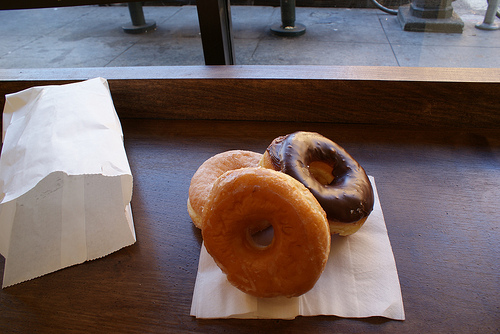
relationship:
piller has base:
[396, 2, 467, 37] [396, 2, 465, 36]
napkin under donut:
[188, 149, 414, 320] [265, 123, 382, 246]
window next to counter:
[4, 6, 500, 77] [2, 65, 499, 334]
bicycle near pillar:
[371, 3, 406, 16] [396, 2, 467, 37]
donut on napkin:
[265, 123, 382, 246] [188, 149, 414, 320]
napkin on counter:
[188, 149, 414, 320] [2, 65, 499, 334]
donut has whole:
[265, 123, 382, 246] [305, 154, 344, 191]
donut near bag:
[192, 166, 337, 306] [0, 72, 145, 287]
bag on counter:
[0, 72, 145, 287] [2, 65, 499, 334]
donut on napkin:
[192, 166, 337, 306] [188, 149, 414, 320]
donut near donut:
[265, 123, 382, 246] [192, 166, 337, 306]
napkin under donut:
[188, 149, 414, 320] [192, 166, 337, 306]